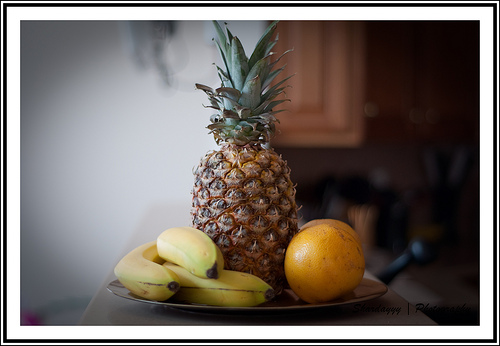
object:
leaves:
[210, 20, 287, 149]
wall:
[135, 122, 257, 187]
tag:
[359, 301, 466, 319]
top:
[194, 20, 293, 137]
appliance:
[375, 231, 435, 287]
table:
[74, 251, 443, 326]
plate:
[100, 276, 389, 314]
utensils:
[423, 138, 495, 253]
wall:
[18, 22, 270, 327]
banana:
[111, 240, 181, 306]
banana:
[153, 221, 221, 281]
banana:
[158, 260, 274, 307]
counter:
[87, 200, 439, 330]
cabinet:
[253, 17, 371, 152]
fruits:
[189, 20, 302, 306]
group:
[284, 216, 366, 306]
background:
[20, 20, 480, 324]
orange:
[283, 218, 366, 300]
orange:
[280, 224, 366, 305]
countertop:
[78, 198, 438, 327]